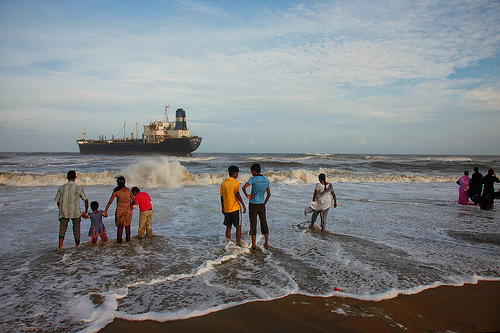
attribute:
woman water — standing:
[300, 170, 346, 245]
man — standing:
[49, 162, 89, 252]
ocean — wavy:
[364, 183, 434, 266]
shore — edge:
[2, 176, 497, 331]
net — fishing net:
[294, 214, 316, 231]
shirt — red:
[129, 181, 155, 240]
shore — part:
[27, 263, 497, 323]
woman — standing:
[107, 176, 131, 239]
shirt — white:
[308, 180, 334, 212]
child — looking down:
[129, 182, 156, 239]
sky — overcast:
[4, 8, 498, 157]